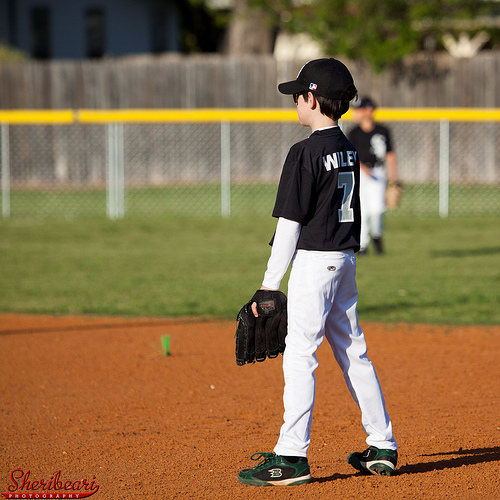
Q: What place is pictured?
A: It is a field.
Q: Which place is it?
A: It is a field.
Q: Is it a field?
A: Yes, it is a field.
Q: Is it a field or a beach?
A: It is a field.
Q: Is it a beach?
A: No, it is a field.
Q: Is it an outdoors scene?
A: Yes, it is outdoors.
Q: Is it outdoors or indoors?
A: It is outdoors.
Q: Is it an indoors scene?
A: No, it is outdoors.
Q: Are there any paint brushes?
A: No, there are no paint brushes.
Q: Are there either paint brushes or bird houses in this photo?
A: No, there are no paint brushes or bird houses.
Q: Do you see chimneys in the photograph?
A: No, there are no chimneys.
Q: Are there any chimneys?
A: No, there are no chimneys.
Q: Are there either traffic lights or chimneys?
A: No, there are no chimneys or traffic lights.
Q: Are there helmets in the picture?
A: No, there are no helmets.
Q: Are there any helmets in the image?
A: No, there are no helmets.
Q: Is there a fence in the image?
A: Yes, there is a fence.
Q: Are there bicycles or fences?
A: Yes, there is a fence.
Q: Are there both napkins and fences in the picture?
A: No, there is a fence but no napkins.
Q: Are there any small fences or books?
A: Yes, there is a small fence.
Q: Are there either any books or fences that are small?
A: Yes, the fence is small.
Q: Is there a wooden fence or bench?
A: Yes, there is a wood fence.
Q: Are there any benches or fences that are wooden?
A: Yes, the fence is wooden.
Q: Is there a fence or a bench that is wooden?
A: Yes, the fence is wooden.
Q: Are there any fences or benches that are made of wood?
A: Yes, the fence is made of wood.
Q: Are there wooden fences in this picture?
A: Yes, there is a wood fence.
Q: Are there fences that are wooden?
A: Yes, there is a fence that is wooden.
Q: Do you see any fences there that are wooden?
A: Yes, there is a fence that is wooden.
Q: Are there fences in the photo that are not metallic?
A: Yes, there is a wooden fence.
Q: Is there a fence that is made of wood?
A: Yes, there is a fence that is made of wood.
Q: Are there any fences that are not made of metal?
A: Yes, there is a fence that is made of wood.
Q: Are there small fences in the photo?
A: Yes, there is a small fence.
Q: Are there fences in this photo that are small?
A: Yes, there is a fence that is small.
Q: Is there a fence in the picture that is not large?
A: Yes, there is a small fence.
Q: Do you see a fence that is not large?
A: Yes, there is a small fence.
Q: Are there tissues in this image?
A: No, there are no tissues.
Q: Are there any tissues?
A: No, there are no tissues.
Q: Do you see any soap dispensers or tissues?
A: No, there are no tissues or soap dispensers.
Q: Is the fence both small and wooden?
A: Yes, the fence is small and wooden.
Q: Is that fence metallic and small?
A: No, the fence is small but wooden.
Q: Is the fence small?
A: Yes, the fence is small.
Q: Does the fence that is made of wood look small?
A: Yes, the fence is small.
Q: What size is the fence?
A: The fence is small.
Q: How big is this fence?
A: The fence is small.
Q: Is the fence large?
A: No, the fence is small.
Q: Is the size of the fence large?
A: No, the fence is small.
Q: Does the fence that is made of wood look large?
A: No, the fence is small.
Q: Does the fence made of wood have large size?
A: No, the fence is small.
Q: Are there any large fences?
A: No, there is a fence but it is small.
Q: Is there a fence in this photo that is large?
A: No, there is a fence but it is small.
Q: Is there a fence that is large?
A: No, there is a fence but it is small.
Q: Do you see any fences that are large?
A: No, there is a fence but it is small.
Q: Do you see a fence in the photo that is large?
A: No, there is a fence but it is small.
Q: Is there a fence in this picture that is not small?
A: No, there is a fence but it is small.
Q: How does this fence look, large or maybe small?
A: The fence is small.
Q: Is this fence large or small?
A: The fence is small.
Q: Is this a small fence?
A: Yes, this is a small fence.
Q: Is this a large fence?
A: No, this is a small fence.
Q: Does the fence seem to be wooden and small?
A: Yes, the fence is wooden and small.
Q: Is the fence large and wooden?
A: No, the fence is wooden but small.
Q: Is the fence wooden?
A: Yes, the fence is wooden.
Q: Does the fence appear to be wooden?
A: Yes, the fence is wooden.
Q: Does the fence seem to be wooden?
A: Yes, the fence is wooden.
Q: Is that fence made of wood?
A: Yes, the fence is made of wood.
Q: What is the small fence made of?
A: The fence is made of wood.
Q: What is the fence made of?
A: The fence is made of wood.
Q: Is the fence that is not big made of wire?
A: No, the fence is made of wood.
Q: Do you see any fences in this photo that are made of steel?
A: No, there is a fence but it is made of wood.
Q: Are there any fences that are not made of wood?
A: No, there is a fence but it is made of wood.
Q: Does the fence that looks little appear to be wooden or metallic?
A: The fence is wooden.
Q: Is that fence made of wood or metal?
A: The fence is made of wood.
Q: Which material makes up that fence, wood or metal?
A: The fence is made of wood.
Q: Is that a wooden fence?
A: Yes, that is a wooden fence.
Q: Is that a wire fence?
A: No, that is a wooden fence.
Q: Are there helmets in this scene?
A: No, there are no helmets.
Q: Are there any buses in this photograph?
A: No, there are no buses.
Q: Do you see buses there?
A: No, there are no buses.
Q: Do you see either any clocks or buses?
A: No, there are no buses or clocks.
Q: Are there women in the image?
A: No, there are no women.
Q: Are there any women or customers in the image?
A: No, there are no women or customers.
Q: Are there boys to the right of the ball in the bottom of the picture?
A: Yes, there is a boy to the right of the ball.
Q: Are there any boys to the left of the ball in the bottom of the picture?
A: No, the boy is to the right of the ball.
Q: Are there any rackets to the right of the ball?
A: No, there is a boy to the right of the ball.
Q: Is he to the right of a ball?
A: Yes, the boy is to the right of a ball.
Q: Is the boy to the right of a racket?
A: No, the boy is to the right of a ball.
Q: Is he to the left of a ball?
A: No, the boy is to the right of a ball.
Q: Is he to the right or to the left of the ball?
A: The boy is to the right of the ball.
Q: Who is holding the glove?
A: The boy is holding the glove.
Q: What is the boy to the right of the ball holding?
A: The boy is holding the glove.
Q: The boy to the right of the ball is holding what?
A: The boy is holding the glove.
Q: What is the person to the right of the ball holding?
A: The boy is holding the glove.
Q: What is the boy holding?
A: The boy is holding the glove.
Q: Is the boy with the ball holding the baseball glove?
A: Yes, the boy is holding the glove.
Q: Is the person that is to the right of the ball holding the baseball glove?
A: Yes, the boy is holding the glove.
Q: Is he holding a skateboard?
A: No, the boy is holding the glove.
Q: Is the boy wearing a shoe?
A: Yes, the boy is wearing a shoe.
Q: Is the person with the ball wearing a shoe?
A: Yes, the boy is wearing a shoe.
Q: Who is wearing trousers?
A: The boy is wearing trousers.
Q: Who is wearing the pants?
A: The boy is wearing trousers.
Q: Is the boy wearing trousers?
A: Yes, the boy is wearing trousers.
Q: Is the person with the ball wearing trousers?
A: Yes, the boy is wearing trousers.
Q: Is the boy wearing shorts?
A: No, the boy is wearing trousers.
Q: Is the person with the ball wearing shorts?
A: No, the boy is wearing trousers.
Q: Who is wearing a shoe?
A: The boy is wearing a shoe.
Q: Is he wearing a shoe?
A: Yes, the boy is wearing a shoe.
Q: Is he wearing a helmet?
A: No, the boy is wearing a shoe.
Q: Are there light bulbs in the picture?
A: No, there are no light bulbs.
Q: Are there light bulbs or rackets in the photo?
A: No, there are no light bulbs or rackets.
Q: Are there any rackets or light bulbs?
A: No, there are no light bulbs or rackets.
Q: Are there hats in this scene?
A: Yes, there is a hat.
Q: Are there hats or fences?
A: Yes, there is a hat.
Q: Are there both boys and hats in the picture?
A: Yes, there are both a hat and a boy.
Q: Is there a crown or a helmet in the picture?
A: No, there are no helmets or crowns.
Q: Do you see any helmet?
A: No, there are no helmets.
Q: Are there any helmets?
A: No, there are no helmets.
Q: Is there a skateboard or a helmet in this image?
A: No, there are no helmets or skateboards.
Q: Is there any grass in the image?
A: Yes, there is grass.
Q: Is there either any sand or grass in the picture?
A: Yes, there is grass.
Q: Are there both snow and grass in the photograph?
A: No, there is grass but no snow.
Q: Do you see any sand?
A: No, there is no sand.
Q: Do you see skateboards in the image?
A: No, there are no skateboards.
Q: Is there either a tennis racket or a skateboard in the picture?
A: No, there are no skateboards or rackets.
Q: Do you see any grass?
A: Yes, there is grass.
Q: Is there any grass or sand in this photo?
A: Yes, there is grass.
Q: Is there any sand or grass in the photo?
A: Yes, there is grass.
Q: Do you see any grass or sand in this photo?
A: Yes, there is grass.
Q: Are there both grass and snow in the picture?
A: No, there is grass but no snow.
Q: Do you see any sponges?
A: No, there are no sponges.